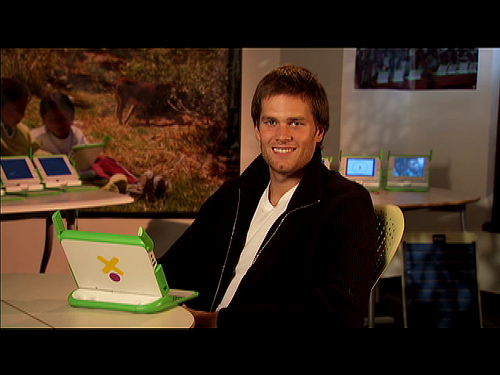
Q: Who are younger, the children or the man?
A: The children are younger than the man.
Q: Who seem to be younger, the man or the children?
A: The children are younger than the man.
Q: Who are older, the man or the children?
A: The man are older than the children.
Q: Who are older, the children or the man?
A: The man are older than the children.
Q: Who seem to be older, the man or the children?
A: The man are older than the children.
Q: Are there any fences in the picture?
A: No, there are no fences.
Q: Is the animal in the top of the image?
A: Yes, the animal is in the top of the image.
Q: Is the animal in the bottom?
A: No, the animal is in the top of the image.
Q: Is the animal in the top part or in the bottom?
A: The animal is in the top of the image.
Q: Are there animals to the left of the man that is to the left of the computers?
A: Yes, there is an animal to the left of the man.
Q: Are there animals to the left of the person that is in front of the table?
A: Yes, there is an animal to the left of the man.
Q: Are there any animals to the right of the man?
A: No, the animal is to the left of the man.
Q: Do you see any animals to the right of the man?
A: No, the animal is to the left of the man.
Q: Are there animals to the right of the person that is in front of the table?
A: No, the animal is to the left of the man.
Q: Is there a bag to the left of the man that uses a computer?
A: No, there is an animal to the left of the man.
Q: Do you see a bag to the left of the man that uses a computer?
A: No, there is an animal to the left of the man.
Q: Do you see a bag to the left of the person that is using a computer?
A: No, there is an animal to the left of the man.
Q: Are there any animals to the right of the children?
A: Yes, there is an animal to the right of the children.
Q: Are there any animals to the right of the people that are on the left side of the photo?
A: Yes, there is an animal to the right of the children.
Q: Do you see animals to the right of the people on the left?
A: Yes, there is an animal to the right of the children.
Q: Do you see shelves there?
A: No, there are no shelves.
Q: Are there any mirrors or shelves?
A: No, there are no shelves or mirrors.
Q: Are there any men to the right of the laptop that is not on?
A: Yes, there is a man to the right of the laptop.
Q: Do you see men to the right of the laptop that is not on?
A: Yes, there is a man to the right of the laptop.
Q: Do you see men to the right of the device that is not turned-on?
A: Yes, there is a man to the right of the laptop.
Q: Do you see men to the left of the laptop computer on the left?
A: No, the man is to the right of the laptop.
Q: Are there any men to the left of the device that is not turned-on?
A: No, the man is to the right of the laptop.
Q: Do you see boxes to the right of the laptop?
A: No, there is a man to the right of the laptop.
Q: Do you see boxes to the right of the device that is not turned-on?
A: No, there is a man to the right of the laptop.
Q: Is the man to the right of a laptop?
A: Yes, the man is to the right of a laptop.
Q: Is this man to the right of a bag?
A: No, the man is to the right of a laptop.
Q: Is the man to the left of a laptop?
A: No, the man is to the right of a laptop.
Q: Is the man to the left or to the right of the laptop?
A: The man is to the right of the laptop.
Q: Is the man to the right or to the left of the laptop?
A: The man is to the right of the laptop.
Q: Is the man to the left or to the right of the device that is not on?
A: The man is to the right of the laptop.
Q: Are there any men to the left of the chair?
A: Yes, there is a man to the left of the chair.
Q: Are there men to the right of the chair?
A: No, the man is to the left of the chair.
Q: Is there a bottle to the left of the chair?
A: No, there is a man to the left of the chair.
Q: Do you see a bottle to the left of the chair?
A: No, there is a man to the left of the chair.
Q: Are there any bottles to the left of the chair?
A: No, there is a man to the left of the chair.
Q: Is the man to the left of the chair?
A: Yes, the man is to the left of the chair.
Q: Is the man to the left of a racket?
A: No, the man is to the left of the chair.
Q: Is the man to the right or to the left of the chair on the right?
A: The man is to the left of the chair.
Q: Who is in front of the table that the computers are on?
A: The man is in front of the table.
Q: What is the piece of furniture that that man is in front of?
A: The piece of furniture is a table.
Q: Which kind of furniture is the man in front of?
A: The man is in front of the table.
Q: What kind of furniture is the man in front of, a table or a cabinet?
A: The man is in front of a table.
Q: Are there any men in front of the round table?
A: Yes, there is a man in front of the table.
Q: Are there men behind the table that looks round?
A: No, the man is in front of the table.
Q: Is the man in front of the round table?
A: Yes, the man is in front of the table.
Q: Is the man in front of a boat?
A: No, the man is in front of the table.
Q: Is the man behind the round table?
A: No, the man is in front of the table.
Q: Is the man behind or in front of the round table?
A: The man is in front of the table.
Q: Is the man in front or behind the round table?
A: The man is in front of the table.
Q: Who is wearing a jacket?
A: The man is wearing a jacket.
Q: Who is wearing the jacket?
A: The man is wearing a jacket.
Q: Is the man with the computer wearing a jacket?
A: Yes, the man is wearing a jacket.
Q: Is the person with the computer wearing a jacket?
A: Yes, the man is wearing a jacket.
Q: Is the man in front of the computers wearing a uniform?
A: No, the man is wearing a jacket.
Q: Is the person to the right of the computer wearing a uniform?
A: No, the man is wearing a jacket.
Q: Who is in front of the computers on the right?
A: The man is in front of the computers.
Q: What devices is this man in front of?
A: The man is in front of the computers.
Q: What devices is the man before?
A: The man is in front of the computers.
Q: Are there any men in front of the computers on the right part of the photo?
A: Yes, there is a man in front of the computers.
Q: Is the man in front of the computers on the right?
A: Yes, the man is in front of the computers.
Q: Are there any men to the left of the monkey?
A: Yes, there is a man to the left of the monkey.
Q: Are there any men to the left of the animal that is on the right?
A: Yes, there is a man to the left of the monkey.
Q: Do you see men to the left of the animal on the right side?
A: Yes, there is a man to the left of the monkey.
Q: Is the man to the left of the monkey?
A: Yes, the man is to the left of the monkey.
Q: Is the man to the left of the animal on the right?
A: Yes, the man is to the left of the monkey.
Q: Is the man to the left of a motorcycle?
A: No, the man is to the left of the monkey.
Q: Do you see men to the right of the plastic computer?
A: Yes, there is a man to the right of the computer.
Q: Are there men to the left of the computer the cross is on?
A: No, the man is to the right of the computer.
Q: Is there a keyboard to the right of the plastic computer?
A: No, there is a man to the right of the computer.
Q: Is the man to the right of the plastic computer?
A: Yes, the man is to the right of the computer.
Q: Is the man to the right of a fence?
A: No, the man is to the right of the computer.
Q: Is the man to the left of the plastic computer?
A: No, the man is to the right of the computer.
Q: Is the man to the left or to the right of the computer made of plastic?
A: The man is to the right of the computer.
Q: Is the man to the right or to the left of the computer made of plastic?
A: The man is to the right of the computer.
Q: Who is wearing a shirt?
A: The man is wearing a shirt.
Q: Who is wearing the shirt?
A: The man is wearing a shirt.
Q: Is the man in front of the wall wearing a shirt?
A: Yes, the man is wearing a shirt.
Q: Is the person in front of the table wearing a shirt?
A: Yes, the man is wearing a shirt.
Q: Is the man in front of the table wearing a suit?
A: No, the man is wearing a shirt.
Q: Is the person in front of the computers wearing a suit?
A: No, the man is wearing a shirt.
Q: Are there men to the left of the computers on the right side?
A: Yes, there is a man to the left of the computers.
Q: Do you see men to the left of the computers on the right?
A: Yes, there is a man to the left of the computers.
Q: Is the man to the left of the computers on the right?
A: Yes, the man is to the left of the computers.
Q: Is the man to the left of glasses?
A: No, the man is to the left of the computers.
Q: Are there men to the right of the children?
A: Yes, there is a man to the right of the children.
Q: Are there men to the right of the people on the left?
A: Yes, there is a man to the right of the children.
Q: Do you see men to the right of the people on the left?
A: Yes, there is a man to the right of the children.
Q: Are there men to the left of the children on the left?
A: No, the man is to the right of the children.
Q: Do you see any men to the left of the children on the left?
A: No, the man is to the right of the children.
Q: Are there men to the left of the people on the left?
A: No, the man is to the right of the children.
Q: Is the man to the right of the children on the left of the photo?
A: Yes, the man is to the right of the children.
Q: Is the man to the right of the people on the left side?
A: Yes, the man is to the right of the children.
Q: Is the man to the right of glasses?
A: No, the man is to the right of the children.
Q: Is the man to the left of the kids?
A: No, the man is to the right of the kids.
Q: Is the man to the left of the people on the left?
A: No, the man is to the right of the kids.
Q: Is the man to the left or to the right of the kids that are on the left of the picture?
A: The man is to the right of the children.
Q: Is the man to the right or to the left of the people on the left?
A: The man is to the right of the children.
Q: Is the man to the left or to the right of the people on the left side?
A: The man is to the right of the children.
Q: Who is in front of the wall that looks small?
A: The man is in front of the wall.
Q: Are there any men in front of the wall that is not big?
A: Yes, there is a man in front of the wall.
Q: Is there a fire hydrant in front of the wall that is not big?
A: No, there is a man in front of the wall.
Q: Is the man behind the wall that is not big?
A: No, the man is in front of the wall.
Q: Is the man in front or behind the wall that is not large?
A: The man is in front of the wall.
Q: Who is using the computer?
A: The man is using the computer.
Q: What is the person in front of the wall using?
A: The man is using a computer.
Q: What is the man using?
A: The man is using a computer.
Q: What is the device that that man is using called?
A: The device is a computer.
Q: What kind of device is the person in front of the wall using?
A: The man is using a computer.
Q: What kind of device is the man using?
A: The man is using a computer.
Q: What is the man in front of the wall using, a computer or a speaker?
A: The man is using a computer.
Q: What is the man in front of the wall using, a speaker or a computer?
A: The man is using a computer.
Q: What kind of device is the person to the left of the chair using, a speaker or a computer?
A: The man is using a computer.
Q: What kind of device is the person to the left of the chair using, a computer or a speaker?
A: The man is using a computer.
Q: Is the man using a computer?
A: Yes, the man is using a computer.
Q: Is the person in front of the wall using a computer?
A: Yes, the man is using a computer.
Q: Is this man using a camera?
A: No, the man is using a computer.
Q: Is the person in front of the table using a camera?
A: No, the man is using a computer.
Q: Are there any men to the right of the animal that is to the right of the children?
A: Yes, there is a man to the right of the animal.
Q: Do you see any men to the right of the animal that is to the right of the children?
A: Yes, there is a man to the right of the animal.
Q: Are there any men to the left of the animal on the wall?
A: No, the man is to the right of the animal.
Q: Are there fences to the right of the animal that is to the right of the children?
A: No, there is a man to the right of the animal.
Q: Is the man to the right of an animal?
A: Yes, the man is to the right of an animal.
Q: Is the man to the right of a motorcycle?
A: No, the man is to the right of an animal.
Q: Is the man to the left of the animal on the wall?
A: No, the man is to the right of the animal.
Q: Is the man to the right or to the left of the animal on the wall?
A: The man is to the right of the animal.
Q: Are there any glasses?
A: No, there are no glasses.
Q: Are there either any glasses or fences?
A: No, there are no glasses or fences.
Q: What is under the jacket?
A: The shirt is under the jacket.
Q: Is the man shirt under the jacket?
A: Yes, the shirt is under the jacket.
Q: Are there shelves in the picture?
A: No, there are no shelves.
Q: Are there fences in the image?
A: No, there are no fences.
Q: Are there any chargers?
A: No, there are no chargers.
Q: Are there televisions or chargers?
A: No, there are no chargers or televisions.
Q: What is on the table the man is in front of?
A: The computers are on the table.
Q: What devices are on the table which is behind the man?
A: The devices are computers.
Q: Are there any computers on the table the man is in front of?
A: Yes, there are computers on the table.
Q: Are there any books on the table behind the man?
A: No, there are computers on the table.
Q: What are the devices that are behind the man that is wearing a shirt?
A: The devices are computers.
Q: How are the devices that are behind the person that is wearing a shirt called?
A: The devices are computers.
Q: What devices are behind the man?
A: The devices are computers.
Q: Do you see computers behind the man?
A: Yes, there are computers behind the man.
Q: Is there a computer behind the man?
A: Yes, there are computers behind the man.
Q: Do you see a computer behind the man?
A: Yes, there are computers behind the man.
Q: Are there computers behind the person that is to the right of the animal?
A: Yes, there are computers behind the man.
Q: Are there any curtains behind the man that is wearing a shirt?
A: No, there are computers behind the man.